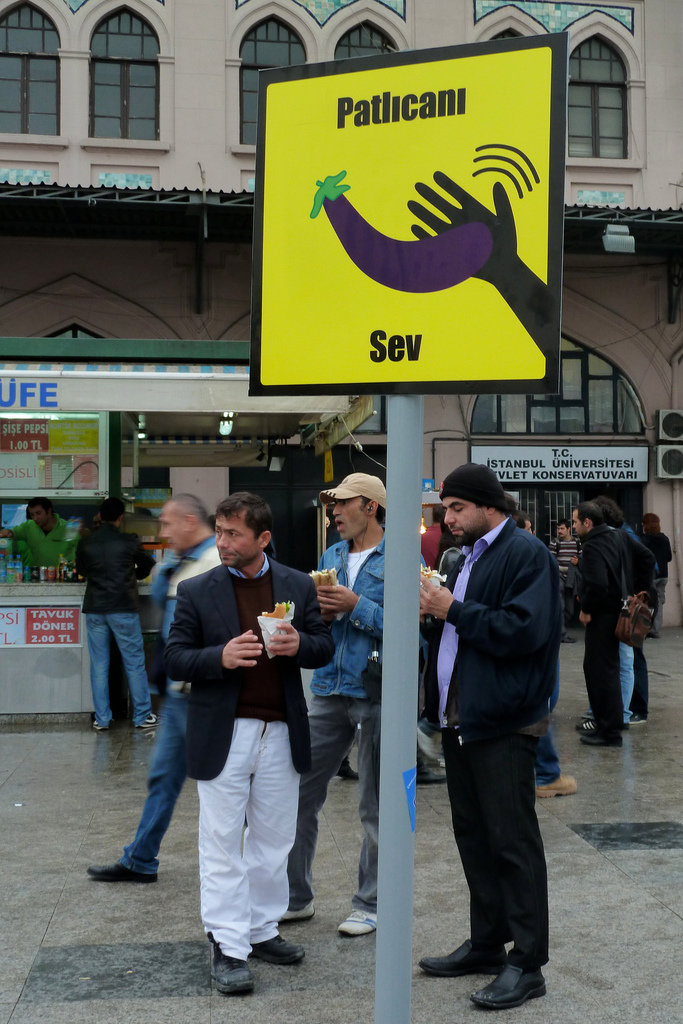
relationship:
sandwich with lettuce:
[259, 599, 288, 617] [284, 598, 293, 615]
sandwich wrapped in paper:
[259, 599, 288, 617] [252, 597, 297, 660]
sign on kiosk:
[25, 602, 80, 643] [2, 332, 380, 719]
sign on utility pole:
[402, 763, 417, 835] [371, 392, 425, 1020]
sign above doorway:
[470, 443, 649, 481] [518, 487, 593, 551]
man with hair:
[562, 501, 627, 738] [571, 500, 605, 524]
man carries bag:
[562, 501, 627, 738] [612, 585, 657, 648]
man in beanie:
[415, 463, 553, 1009] [439, 460, 504, 503]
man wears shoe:
[415, 463, 553, 1009] [468, 958, 546, 1010]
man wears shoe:
[415, 463, 553, 1009] [420, 936, 508, 976]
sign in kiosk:
[47, 416, 98, 453] [2, 332, 380, 719]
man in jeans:
[68, 497, 157, 732] [81, 608, 155, 728]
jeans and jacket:
[81, 608, 155, 728] [73, 522, 154, 613]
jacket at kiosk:
[73, 522, 154, 613] [2, 332, 380, 719]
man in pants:
[547, 517, 584, 625] [561, 576, 577, 626]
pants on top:
[561, 576, 577, 626] [546, 533, 582, 575]